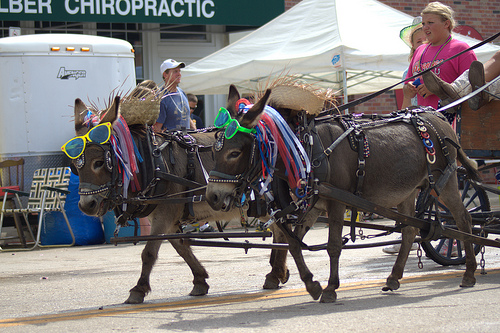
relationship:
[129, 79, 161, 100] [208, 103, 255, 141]
donkey wearing sunglasses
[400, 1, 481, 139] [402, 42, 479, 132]
woman wearing shirt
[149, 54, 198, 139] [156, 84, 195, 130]
man in shirt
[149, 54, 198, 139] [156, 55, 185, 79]
man wearing hat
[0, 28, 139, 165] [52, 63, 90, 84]
trailer with logo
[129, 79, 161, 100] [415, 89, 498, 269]
donkey pulling cart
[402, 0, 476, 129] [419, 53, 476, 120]
woman wearing boots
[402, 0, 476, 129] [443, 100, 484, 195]
woman wearing jeans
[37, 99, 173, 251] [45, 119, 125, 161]
donkey wearing sunglasses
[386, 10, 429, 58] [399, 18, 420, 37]
woman wearing hat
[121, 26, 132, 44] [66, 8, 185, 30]
window on the building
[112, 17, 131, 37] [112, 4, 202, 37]
window on the building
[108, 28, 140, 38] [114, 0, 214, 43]
window on the building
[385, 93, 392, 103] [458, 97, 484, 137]
brick in a wall